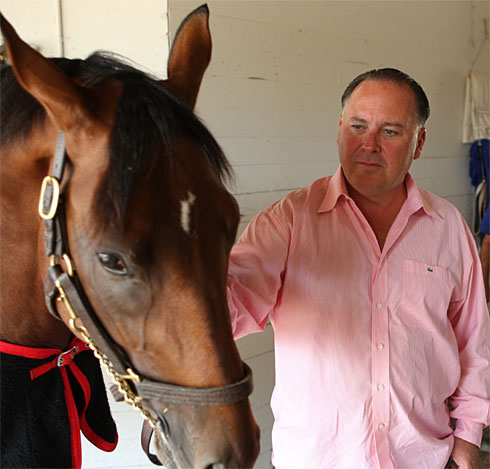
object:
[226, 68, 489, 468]
person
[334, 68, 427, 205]
head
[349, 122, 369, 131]
eye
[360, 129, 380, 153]
nose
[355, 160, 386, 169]
mouth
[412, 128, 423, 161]
ear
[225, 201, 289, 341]
arm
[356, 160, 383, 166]
lip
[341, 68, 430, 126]
hair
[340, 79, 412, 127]
forehead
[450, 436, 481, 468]
hand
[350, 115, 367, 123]
eyebrow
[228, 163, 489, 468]
shirt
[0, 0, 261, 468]
horse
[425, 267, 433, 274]
logo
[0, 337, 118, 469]
blanket